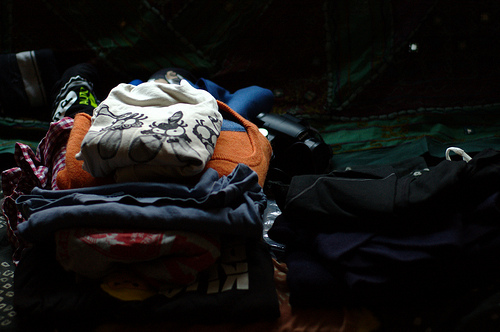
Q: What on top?
A: A shirt.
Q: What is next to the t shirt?
A: A bag.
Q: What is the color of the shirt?
A: White.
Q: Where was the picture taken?
A: In the laundry.